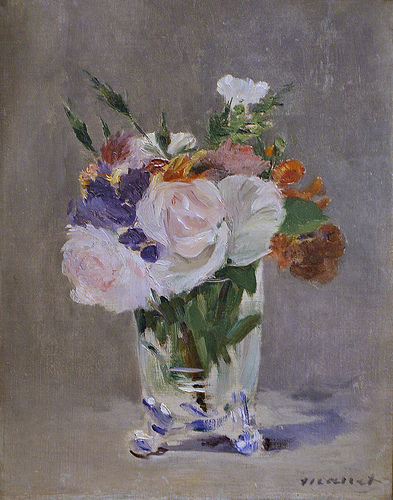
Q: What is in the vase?
A: Flowers.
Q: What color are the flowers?
A: White, blue and orange.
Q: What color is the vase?
A: It is clear.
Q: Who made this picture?
A: An artist.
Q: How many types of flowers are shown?
A: Three.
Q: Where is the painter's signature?
A: Right corner.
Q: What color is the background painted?
A: Grey.